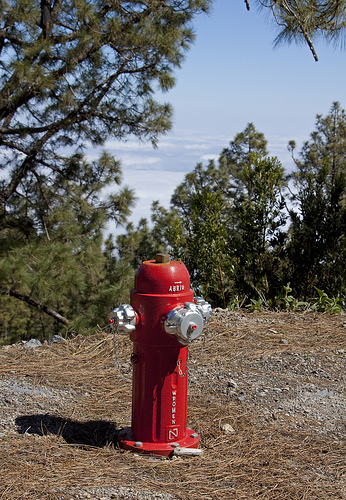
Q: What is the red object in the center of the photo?
A: Fire hydrant.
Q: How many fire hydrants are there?
A: One.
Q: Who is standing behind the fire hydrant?
A: No one.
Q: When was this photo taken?
A: Daytime.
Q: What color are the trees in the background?
A: Green.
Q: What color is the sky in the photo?
A: Blue.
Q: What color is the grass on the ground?
A: Brown.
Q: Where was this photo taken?
A: At the park.